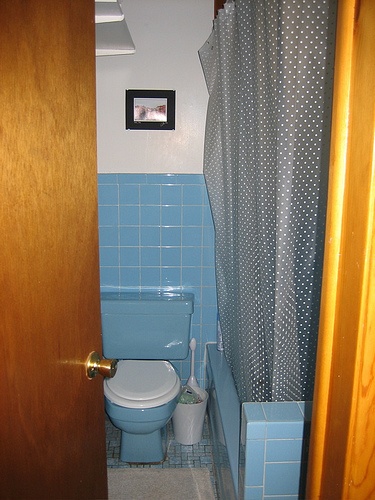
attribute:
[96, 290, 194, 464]
toilet — clean, blue, light blue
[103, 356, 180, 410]
lid — closed, white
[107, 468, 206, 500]
mat — white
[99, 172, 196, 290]
tile — blue, ceramic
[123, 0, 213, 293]
wall — white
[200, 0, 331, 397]
curtain — grey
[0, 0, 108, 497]
door — open, wooden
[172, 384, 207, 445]
trash can — full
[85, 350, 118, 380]
knob — brass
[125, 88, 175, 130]
picture — little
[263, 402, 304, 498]
tiles — blue